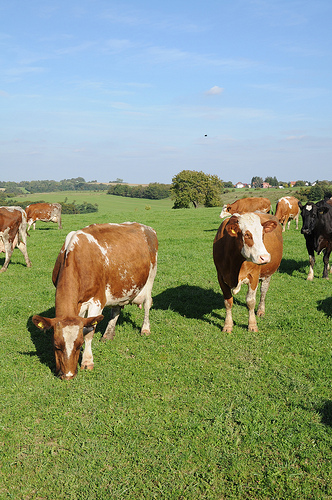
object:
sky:
[0, 0, 332, 186]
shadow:
[149, 285, 258, 331]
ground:
[0, 186, 332, 499]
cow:
[213, 211, 283, 334]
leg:
[221, 287, 234, 327]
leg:
[246, 283, 258, 325]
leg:
[257, 276, 271, 314]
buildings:
[235, 182, 246, 190]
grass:
[0, 187, 332, 500]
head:
[226, 213, 277, 266]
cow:
[298, 200, 332, 282]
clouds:
[0, 0, 332, 185]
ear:
[225, 222, 239, 237]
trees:
[168, 169, 225, 209]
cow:
[32, 221, 160, 381]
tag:
[38, 321, 45, 328]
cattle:
[25, 202, 63, 232]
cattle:
[0, 206, 32, 274]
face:
[239, 212, 271, 265]